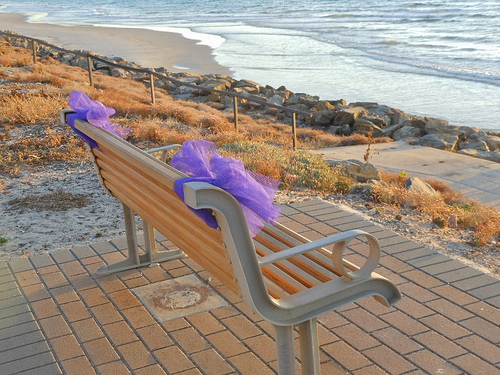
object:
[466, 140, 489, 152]
rocks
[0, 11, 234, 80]
shore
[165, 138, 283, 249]
bow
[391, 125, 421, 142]
rock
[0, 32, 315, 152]
rail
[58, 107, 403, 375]
bench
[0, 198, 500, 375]
patio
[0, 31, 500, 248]
grass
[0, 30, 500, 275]
sand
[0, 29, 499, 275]
area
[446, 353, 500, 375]
bricks